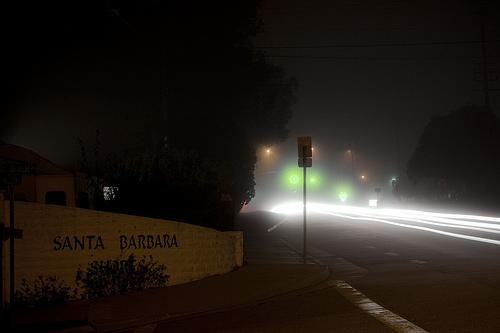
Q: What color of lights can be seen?
A: Green and white.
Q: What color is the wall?
A: White.